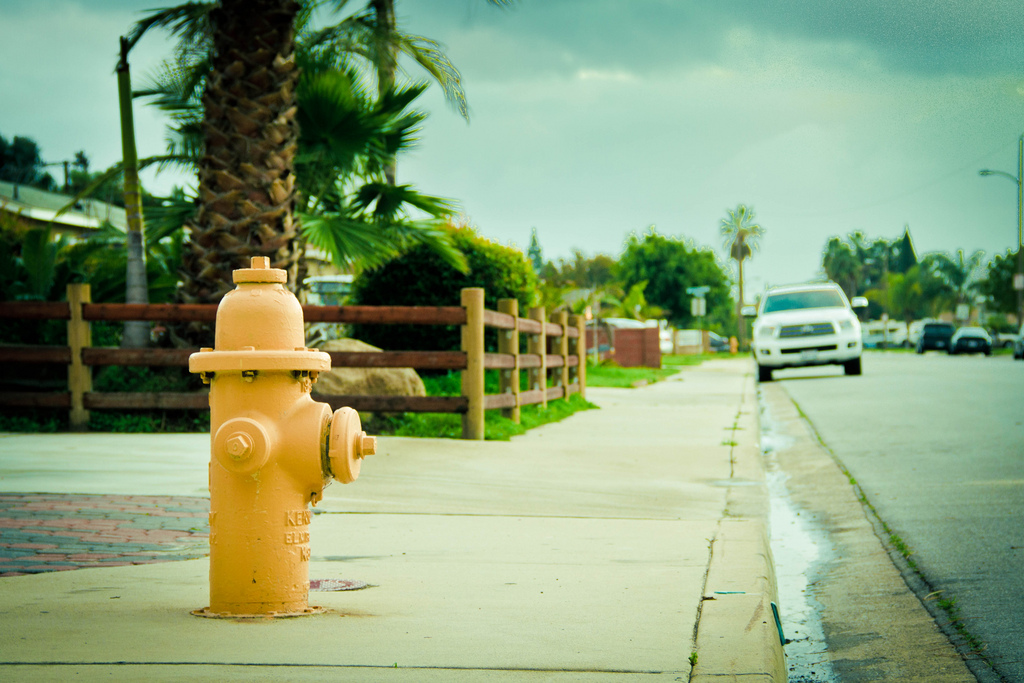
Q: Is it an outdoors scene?
A: Yes, it is outdoors.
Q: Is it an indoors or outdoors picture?
A: It is outdoors.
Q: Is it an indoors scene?
A: No, it is outdoors.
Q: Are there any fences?
A: Yes, there is a fence.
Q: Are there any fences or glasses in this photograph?
A: Yes, there is a fence.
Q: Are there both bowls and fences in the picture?
A: No, there is a fence but no bowls.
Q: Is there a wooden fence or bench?
A: Yes, there is a wood fence.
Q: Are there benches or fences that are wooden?
A: Yes, the fence is wooden.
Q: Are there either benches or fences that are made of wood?
A: Yes, the fence is made of wood.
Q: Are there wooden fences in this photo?
A: Yes, there is a wood fence.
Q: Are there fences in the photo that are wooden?
A: Yes, there is a fence that is wooden.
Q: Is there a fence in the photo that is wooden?
A: Yes, there is a fence that is wooden.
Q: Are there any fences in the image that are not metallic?
A: Yes, there is a wooden fence.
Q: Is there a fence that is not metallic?
A: Yes, there is a wooden fence.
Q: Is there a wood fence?
A: Yes, there is a fence that is made of wood.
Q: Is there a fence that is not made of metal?
A: Yes, there is a fence that is made of wood.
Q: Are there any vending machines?
A: No, there are no vending machines.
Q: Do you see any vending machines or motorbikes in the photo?
A: No, there are no vending machines or motorbikes.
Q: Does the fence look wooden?
A: Yes, the fence is wooden.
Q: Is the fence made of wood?
A: Yes, the fence is made of wood.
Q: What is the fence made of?
A: The fence is made of wood.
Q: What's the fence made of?
A: The fence is made of wood.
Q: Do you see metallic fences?
A: No, there is a fence but it is wooden.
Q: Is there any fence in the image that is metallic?
A: No, there is a fence but it is wooden.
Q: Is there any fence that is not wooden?
A: No, there is a fence but it is wooden.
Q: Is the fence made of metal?
A: No, the fence is made of wood.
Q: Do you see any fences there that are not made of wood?
A: No, there is a fence but it is made of wood.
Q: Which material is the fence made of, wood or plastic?
A: The fence is made of wood.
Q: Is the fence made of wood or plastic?
A: The fence is made of wood.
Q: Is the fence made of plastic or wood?
A: The fence is made of wood.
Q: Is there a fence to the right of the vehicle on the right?
A: No, the fence is to the left of the truck.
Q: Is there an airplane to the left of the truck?
A: No, there is a fence to the left of the truck.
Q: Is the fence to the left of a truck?
A: Yes, the fence is to the left of a truck.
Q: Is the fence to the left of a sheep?
A: No, the fence is to the left of a truck.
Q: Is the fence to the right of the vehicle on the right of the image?
A: No, the fence is to the left of the truck.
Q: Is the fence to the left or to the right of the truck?
A: The fence is to the left of the truck.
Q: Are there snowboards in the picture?
A: No, there are no snowboards.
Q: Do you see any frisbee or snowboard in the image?
A: No, there are no snowboards or frisbees.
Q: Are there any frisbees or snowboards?
A: No, there are no snowboards or frisbees.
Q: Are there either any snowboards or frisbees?
A: No, there are no snowboards or frisbees.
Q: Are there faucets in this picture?
A: No, there are no faucets.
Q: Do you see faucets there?
A: No, there are no faucets.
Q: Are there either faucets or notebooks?
A: No, there are no faucets or notebooks.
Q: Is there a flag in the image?
A: No, there are no flags.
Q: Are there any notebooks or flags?
A: No, there are no flags or notebooks.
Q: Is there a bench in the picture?
A: No, there are no benches.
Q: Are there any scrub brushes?
A: No, there are no scrub brushes.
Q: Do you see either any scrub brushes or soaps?
A: No, there are no scrub brushes or soaps.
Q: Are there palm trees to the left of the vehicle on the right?
A: Yes, there is a palm tree to the left of the truck.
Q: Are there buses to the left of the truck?
A: No, there is a palm tree to the left of the truck.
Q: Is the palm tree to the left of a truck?
A: Yes, the palm tree is to the left of a truck.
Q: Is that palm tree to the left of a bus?
A: No, the palm tree is to the left of a truck.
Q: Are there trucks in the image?
A: Yes, there is a truck.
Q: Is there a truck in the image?
A: Yes, there is a truck.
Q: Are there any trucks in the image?
A: Yes, there is a truck.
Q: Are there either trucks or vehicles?
A: Yes, there is a truck.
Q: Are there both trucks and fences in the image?
A: Yes, there are both a truck and a fence.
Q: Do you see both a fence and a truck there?
A: Yes, there are both a truck and a fence.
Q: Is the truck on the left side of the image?
A: No, the truck is on the right of the image.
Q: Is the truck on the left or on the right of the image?
A: The truck is on the right of the image.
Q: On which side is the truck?
A: The truck is on the right of the image.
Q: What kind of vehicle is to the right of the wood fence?
A: The vehicle is a truck.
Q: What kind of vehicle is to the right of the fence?
A: The vehicle is a truck.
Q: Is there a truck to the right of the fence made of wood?
A: Yes, there is a truck to the right of the fence.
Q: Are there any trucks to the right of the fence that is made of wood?
A: Yes, there is a truck to the right of the fence.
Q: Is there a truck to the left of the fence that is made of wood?
A: No, the truck is to the right of the fence.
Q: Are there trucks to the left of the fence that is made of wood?
A: No, the truck is to the right of the fence.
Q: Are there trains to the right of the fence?
A: No, there is a truck to the right of the fence.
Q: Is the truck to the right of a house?
A: No, the truck is to the right of the fence.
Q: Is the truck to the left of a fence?
A: No, the truck is to the right of a fence.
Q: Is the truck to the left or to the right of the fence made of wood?
A: The truck is to the right of the fence.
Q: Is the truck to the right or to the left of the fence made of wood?
A: The truck is to the right of the fence.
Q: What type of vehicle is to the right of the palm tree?
A: The vehicle is a truck.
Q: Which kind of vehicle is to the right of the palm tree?
A: The vehicle is a truck.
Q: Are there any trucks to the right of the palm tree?
A: Yes, there is a truck to the right of the palm tree.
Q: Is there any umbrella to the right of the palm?
A: No, there is a truck to the right of the palm.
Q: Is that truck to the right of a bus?
A: No, the truck is to the right of a palm tree.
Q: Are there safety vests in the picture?
A: No, there are no safety vests.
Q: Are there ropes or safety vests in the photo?
A: No, there are no safety vests or ropes.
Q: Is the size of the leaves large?
A: Yes, the leaves are large.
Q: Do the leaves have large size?
A: Yes, the leaves are large.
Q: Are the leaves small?
A: No, the leaves are large.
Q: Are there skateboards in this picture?
A: No, there are no skateboards.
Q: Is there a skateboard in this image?
A: No, there are no skateboards.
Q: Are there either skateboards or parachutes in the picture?
A: No, there are no skateboards or parachutes.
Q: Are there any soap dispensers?
A: No, there are no soap dispensers.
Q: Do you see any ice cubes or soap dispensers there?
A: No, there are no soap dispensers or ice cubes.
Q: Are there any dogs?
A: No, there are no dogs.